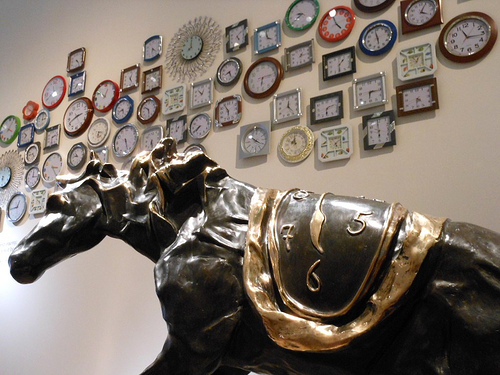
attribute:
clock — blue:
[350, 13, 405, 59]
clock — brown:
[431, 12, 484, 69]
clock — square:
[60, 45, 94, 80]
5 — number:
[341, 203, 381, 248]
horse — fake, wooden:
[8, 127, 494, 372]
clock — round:
[243, 56, 290, 98]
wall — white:
[9, 48, 494, 370]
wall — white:
[4, 5, 489, 373]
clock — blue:
[359, 14, 403, 72]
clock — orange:
[313, 2, 372, 53]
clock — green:
[282, 2, 332, 37]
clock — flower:
[14, 88, 53, 131]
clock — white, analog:
[28, 73, 75, 114]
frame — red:
[38, 71, 82, 120]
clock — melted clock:
[241, 176, 447, 356]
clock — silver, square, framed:
[231, 119, 281, 169]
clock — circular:
[434, 4, 499, 74]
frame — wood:
[434, 10, 497, 70]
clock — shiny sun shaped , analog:
[156, 15, 234, 85]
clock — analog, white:
[0, 110, 22, 147]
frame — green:
[1, 112, 24, 147]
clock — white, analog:
[85, 74, 122, 119]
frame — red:
[83, 77, 123, 115]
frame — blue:
[105, 95, 139, 126]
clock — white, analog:
[104, 87, 139, 131]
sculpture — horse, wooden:
[10, 136, 498, 374]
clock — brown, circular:
[436, 8, 497, 75]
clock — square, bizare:
[389, 33, 442, 80]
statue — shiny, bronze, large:
[17, 143, 490, 371]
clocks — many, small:
[0, 7, 498, 235]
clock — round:
[435, 6, 497, 68]